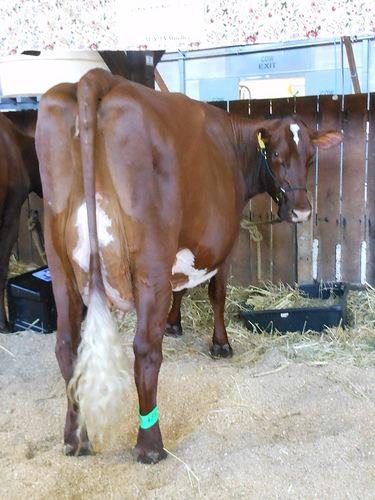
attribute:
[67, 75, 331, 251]
cow — standing, brown, looking, watching, eating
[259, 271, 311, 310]
hay — brown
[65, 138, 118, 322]
tail — brown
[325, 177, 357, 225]
fence — wooden, brown